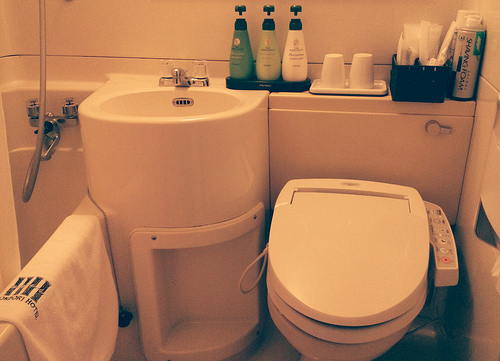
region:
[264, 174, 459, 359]
A white toilet with controls on the side.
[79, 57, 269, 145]
A white sink.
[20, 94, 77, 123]
Silver knobs to a shower.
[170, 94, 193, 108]
Silver drain in a sink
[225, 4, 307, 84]
Three bottles sitting to the right of a sink.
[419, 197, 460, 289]
Controls to a toilet.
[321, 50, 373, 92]
Two stacks of cups on the back of a toilet.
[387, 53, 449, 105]
A black caddy on the toilet.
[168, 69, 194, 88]
A faucet on the sink.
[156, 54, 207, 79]
Clear knobs on a sink.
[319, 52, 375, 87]
two white cups turned upside down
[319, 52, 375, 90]
two white cups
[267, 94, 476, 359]
white toilet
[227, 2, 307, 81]
personal care products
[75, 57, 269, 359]
white sink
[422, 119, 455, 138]
silver knob for flushing the toilet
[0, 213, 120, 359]
white hotel towel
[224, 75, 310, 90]
black tray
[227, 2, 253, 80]
personal care product in green bottle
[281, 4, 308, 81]
personal care product in white bottle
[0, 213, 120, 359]
white cloth floor bathmat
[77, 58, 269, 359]
white sink in the bathroom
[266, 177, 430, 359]
closed lid on the bathroom's toilet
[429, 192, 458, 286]
functional handle with buttons beside the toilet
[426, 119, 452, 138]
flush knob on the tank behind the toilet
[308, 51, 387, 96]
two white cups on a tray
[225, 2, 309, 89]
three personal care bottles on a green tray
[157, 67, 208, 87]
stainless steel faucet on bathroom's sink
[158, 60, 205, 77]
two knobs on the faucet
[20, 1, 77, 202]
water line to shower head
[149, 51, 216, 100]
sink faucet in bathroom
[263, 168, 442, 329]
closed white commode lid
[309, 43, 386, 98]
two white plastic cups turned upside down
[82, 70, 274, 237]
small white bathroom sink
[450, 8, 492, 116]
white can of shaving cream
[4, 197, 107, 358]
white towel with blue design over edge of tub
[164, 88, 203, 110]
small silver drain palte in bathroom sink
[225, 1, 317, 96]
three pump top bottles on bathroom sink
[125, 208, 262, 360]
storage area under sink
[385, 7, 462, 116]
plastic box with paper products in it